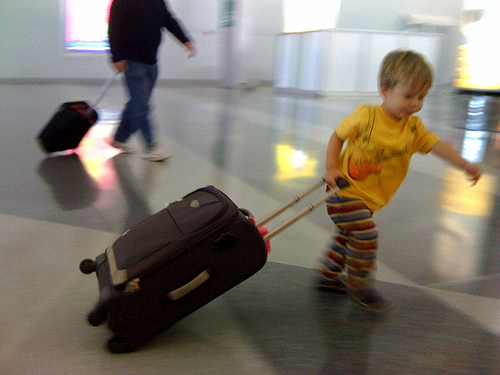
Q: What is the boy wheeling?
A: A suitcase.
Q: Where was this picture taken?
A: In an airport.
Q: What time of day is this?
A: The afternoon.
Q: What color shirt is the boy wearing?
A: Yellow.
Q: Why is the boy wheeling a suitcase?
A: He is traveling.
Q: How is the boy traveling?
A: By plane.